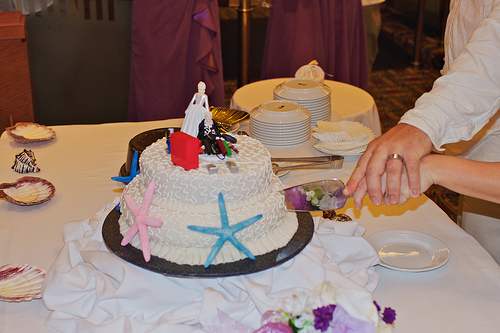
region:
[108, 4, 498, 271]
married couple cutting wedding cake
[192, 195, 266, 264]
blue starfish cake decoration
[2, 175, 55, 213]
sea shell table wedding decoration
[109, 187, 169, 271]
pink starfish wedding cake decoration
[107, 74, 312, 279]
small sea-themed wedding cake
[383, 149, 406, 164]
man's wedding ring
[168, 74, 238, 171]
heterosexual wedding cake topper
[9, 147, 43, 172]
whelk sea shell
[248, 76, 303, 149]
two stacks of white cake serving plates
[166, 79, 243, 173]
scuba diving honeymoon themed wedding topper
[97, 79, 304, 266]
A small wedding cake.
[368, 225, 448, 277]
A small white saucer.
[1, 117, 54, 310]
Seashells.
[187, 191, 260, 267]
A blue starfish.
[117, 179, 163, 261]
A light pink starfish.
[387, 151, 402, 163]
A ring.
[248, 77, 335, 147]
Two stacks of round white saucers.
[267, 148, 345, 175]
A silver pair of tongs.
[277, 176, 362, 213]
A silver cake spatula.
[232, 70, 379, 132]
A small round table with a white tablecloth.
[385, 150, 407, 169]
a ring on a man's hand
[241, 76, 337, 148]
two set of white plates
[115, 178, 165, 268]
a pink starfish on the side of a cake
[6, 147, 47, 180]
a black and white shell on the table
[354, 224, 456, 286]
a white plate on the table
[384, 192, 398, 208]
a fingernail of a man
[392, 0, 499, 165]
part of a white shirt on a man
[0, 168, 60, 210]
a seashell laying on the table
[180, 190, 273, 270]
a blue starfish on the side of a cake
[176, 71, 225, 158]
a bride and groom on the top of the cake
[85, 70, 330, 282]
a wedding cake being cut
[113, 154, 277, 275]
Starfish on a cake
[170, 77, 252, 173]
Figurines on a cake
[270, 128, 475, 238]
People cutting a cake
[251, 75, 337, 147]
Two stacks of plates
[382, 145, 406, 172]
A ring on a man's hand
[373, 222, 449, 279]
A plate on a table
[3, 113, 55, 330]
Sea shells on a table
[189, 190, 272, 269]
A blue star fish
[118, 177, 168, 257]
A pink star fish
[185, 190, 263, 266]
blue star on wedding cake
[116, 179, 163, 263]
pink star on cake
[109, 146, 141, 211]
bright blue star on cake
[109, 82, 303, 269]
wedding cake being cut by bride and groom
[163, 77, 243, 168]
wedding cake topper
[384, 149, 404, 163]
wedding band on male hand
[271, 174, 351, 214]
knife being used to cut cake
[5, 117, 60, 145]
seashell on table cloth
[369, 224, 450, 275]
white saucer under couples hands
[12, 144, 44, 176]
seashell on table